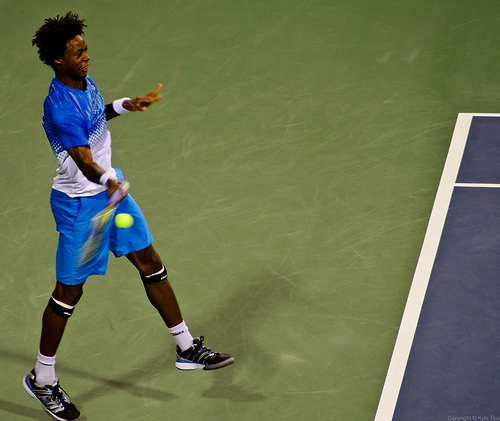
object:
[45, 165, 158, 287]
shorts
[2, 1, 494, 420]
court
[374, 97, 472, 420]
line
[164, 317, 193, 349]
sock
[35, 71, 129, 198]
shirt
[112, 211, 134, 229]
ball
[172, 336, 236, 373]
shoe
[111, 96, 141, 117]
wrist band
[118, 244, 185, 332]
leg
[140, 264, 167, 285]
band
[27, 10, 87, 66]
hair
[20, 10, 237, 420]
man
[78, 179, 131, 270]
racket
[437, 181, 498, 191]
line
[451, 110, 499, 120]
line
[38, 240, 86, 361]
leg